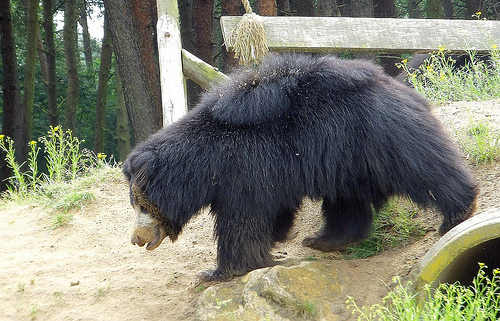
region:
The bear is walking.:
[93, 42, 488, 278]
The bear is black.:
[224, 136, 274, 196]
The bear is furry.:
[159, 101, 382, 178]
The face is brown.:
[112, 182, 173, 249]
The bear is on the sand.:
[36, 243, 150, 319]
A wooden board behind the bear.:
[276, 9, 498, 70]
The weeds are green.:
[408, 274, 498, 319]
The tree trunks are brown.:
[93, 17, 150, 139]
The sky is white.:
[58, 7, 110, 42]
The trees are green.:
[11, 12, 64, 112]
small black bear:
[102, 38, 487, 275]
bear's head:
[99, 140, 210, 266]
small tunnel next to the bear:
[399, 166, 499, 276]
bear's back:
[177, 48, 383, 170]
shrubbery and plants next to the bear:
[3, 113, 134, 223]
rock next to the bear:
[177, 256, 424, 317]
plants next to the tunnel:
[309, 247, 492, 315]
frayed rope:
[226, 0, 288, 85]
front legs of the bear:
[205, 170, 302, 267]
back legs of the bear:
[305, 145, 484, 278]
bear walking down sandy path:
[86, 38, 496, 285]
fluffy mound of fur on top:
[201, 35, 381, 136]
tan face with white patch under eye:
[102, 160, 173, 261]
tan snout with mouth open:
[126, 205, 166, 260]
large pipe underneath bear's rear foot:
[390, 155, 495, 315]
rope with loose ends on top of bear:
[220, 2, 280, 83]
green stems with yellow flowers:
[0, 115, 91, 182]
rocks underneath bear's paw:
[190, 247, 340, 312]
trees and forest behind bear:
[15, 22, 201, 209]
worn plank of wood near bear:
[207, 10, 492, 57]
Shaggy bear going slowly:
[121, 47, 476, 270]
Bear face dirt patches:
[116, 187, 190, 262]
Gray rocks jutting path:
[162, 253, 347, 318]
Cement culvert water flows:
[411, 200, 499, 318]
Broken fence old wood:
[157, 5, 237, 122]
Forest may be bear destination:
[7, 0, 150, 128]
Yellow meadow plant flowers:
[2, 125, 109, 189]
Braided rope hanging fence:
[218, 0, 279, 70]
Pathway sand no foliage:
[7, 213, 206, 319]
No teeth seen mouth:
[123, 214, 177, 259]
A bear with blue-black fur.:
[121, 57, 477, 263]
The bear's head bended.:
[121, 143, 187, 253]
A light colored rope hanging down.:
[225, 0, 277, 62]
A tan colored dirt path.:
[1, 250, 176, 318]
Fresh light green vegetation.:
[339, 261, 497, 319]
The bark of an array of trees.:
[2, 1, 144, 122]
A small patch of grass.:
[468, 128, 498, 185]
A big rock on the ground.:
[181, 269, 343, 319]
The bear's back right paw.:
[297, 225, 379, 252]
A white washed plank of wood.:
[271, 15, 498, 55]